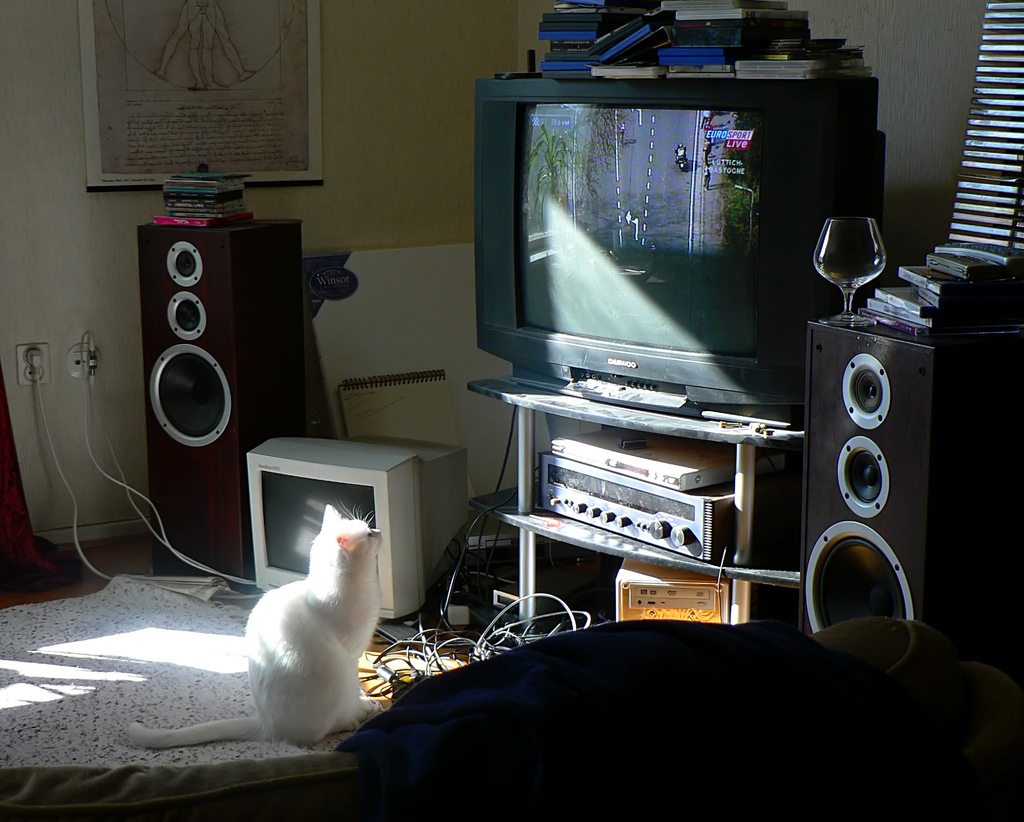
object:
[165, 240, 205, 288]
part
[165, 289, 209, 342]
part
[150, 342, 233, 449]
part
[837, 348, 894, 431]
part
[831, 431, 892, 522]
part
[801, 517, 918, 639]
part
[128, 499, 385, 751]
cat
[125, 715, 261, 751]
tail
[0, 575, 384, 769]
rug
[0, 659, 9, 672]
spots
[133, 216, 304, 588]
large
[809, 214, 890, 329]
glass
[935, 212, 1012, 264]
cd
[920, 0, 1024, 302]
rack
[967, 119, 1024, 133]
cd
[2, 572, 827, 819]
floor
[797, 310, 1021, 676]
speaker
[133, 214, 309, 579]
speaker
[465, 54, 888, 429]
tv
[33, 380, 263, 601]
cord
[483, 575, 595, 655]
cord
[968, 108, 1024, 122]
cds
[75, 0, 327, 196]
painting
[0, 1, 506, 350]
wall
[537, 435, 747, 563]
dvd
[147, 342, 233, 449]
circle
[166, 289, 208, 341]
circle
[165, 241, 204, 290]
circle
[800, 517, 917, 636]
circle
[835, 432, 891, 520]
circle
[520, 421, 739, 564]
vhs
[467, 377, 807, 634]
entertainment center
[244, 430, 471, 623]
monitor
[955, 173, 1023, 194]
cd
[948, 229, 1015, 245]
cd